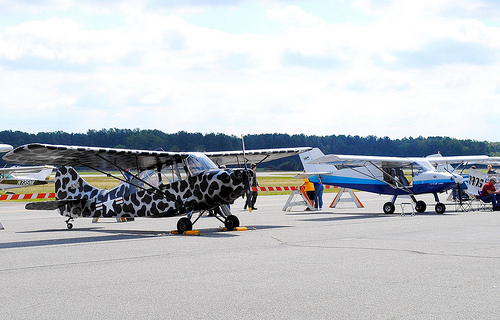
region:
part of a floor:
[370, 256, 403, 291]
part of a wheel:
[218, 186, 246, 243]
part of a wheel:
[408, 181, 440, 218]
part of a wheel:
[376, 200, 399, 228]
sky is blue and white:
[89, 31, 289, 99]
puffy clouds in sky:
[106, 23, 301, 114]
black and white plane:
[71, 161, 221, 226]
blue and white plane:
[271, 138, 431, 205]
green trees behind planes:
[41, 143, 401, 158]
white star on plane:
[86, 186, 138, 223]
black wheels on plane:
[158, 206, 234, 256]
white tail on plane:
[298, 136, 324, 186]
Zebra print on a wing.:
[226, 175, 273, 216]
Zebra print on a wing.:
[293, 145, 405, 200]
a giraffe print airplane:
[1, 140, 316, 237]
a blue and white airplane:
[296, 142, 489, 208]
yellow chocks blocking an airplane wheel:
[166, 226, 200, 239]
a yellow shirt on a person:
[302, 177, 313, 192]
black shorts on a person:
[305, 188, 315, 200]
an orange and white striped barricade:
[254, 179, 365, 212]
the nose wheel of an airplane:
[433, 198, 446, 215]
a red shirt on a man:
[479, 180, 496, 200]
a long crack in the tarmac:
[248, 226, 498, 265]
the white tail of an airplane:
[296, 144, 338, 177]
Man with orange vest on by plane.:
[300, 182, 337, 216]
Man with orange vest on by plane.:
[373, 32, 467, 80]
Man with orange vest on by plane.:
[85, 122, 190, 226]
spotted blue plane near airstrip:
[48, 117, 246, 240]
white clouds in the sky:
[0, 4, 491, 130]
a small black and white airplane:
[16, 142, 265, 232]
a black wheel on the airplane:
[383, 200, 397, 212]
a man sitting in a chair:
[478, 178, 499, 205]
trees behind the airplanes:
[6, 130, 495, 170]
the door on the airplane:
[383, 166, 415, 184]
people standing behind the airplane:
[301, 170, 326, 207]